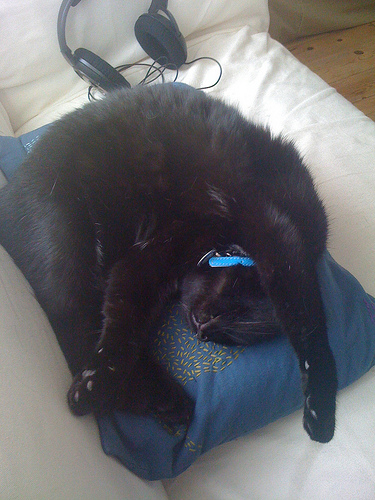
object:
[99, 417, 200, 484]
sheet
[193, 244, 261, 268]
collar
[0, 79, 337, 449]
cat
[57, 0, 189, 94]
headphones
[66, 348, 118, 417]
paw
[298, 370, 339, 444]
paw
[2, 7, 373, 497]
couch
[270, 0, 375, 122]
floor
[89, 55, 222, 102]
wires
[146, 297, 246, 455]
pattern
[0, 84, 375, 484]
pillow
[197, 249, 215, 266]
tag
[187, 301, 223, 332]
mouth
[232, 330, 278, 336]
whiskars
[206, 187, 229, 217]
white hairs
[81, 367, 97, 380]
pads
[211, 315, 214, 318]
tooth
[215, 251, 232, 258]
buckle